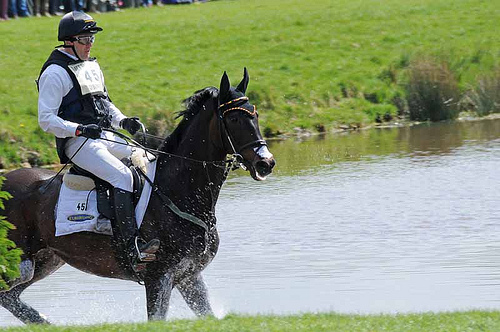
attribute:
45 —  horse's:
[70, 199, 90, 212]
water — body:
[292, 130, 473, 304]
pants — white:
[64, 137, 134, 194]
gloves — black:
[69, 118, 154, 143]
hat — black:
[261, 155, 322, 188]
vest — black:
[38, 57, 151, 161]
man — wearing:
[30, 60, 172, 280]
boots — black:
[104, 180, 171, 300]